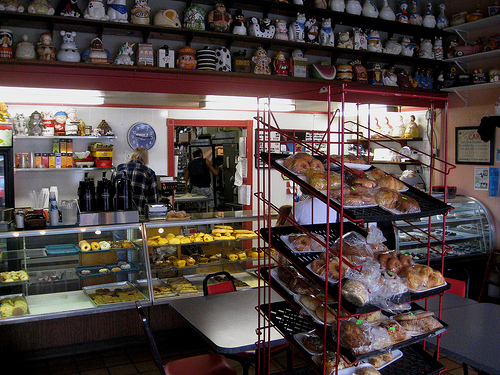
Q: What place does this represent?
A: It represents the bakery.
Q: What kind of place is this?
A: It is a bakery.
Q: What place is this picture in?
A: It is at the bakery.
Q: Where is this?
A: This is at the bakery.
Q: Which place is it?
A: It is a bakery.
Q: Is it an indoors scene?
A: Yes, it is indoors.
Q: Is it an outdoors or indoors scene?
A: It is indoors.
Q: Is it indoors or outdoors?
A: It is indoors.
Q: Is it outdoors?
A: No, it is indoors.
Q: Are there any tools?
A: No, there are no tools.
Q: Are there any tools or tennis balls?
A: No, there are no tools or tennis balls.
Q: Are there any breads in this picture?
A: Yes, there is a bread.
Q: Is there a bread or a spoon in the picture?
A: Yes, there is a bread.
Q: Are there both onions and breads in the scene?
A: No, there is a bread but no onions.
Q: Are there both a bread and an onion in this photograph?
A: No, there is a bread but no onions.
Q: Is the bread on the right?
A: Yes, the bread is on the right of the image.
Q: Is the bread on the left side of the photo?
A: No, the bread is on the right of the image.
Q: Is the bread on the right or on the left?
A: The bread is on the right of the image.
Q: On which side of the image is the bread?
A: The bread is on the right of the image.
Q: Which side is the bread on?
A: The bread is on the right of the image.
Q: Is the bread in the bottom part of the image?
A: Yes, the bread is in the bottom of the image.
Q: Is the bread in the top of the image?
A: No, the bread is in the bottom of the image.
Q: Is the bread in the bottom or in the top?
A: The bread is in the bottom of the image.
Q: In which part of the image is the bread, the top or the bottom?
A: The bread is in the bottom of the image.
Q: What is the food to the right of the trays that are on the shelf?
A: The food is a bread.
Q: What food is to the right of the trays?
A: The food is a bread.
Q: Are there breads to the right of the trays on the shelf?
A: Yes, there is a bread to the right of the trays.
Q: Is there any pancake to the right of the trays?
A: No, there is a bread to the right of the trays.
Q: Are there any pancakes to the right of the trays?
A: No, there is a bread to the right of the trays.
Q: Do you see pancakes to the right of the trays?
A: No, there is a bread to the right of the trays.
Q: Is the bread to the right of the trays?
A: Yes, the bread is to the right of the trays.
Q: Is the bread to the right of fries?
A: No, the bread is to the right of the trays.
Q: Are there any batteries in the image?
A: No, there are no batteries.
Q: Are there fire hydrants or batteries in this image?
A: No, there are no batteries or fire hydrants.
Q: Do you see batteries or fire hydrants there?
A: No, there are no batteries or fire hydrants.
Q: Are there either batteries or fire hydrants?
A: No, there are no batteries or fire hydrants.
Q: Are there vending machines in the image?
A: No, there are no vending machines.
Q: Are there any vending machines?
A: No, there are no vending machines.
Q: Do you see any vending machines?
A: No, there are no vending machines.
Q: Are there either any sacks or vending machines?
A: No, there are no vending machines or sacks.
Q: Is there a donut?
A: Yes, there is a donut.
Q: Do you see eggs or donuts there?
A: Yes, there is a donut.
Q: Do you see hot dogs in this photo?
A: No, there are no hot dogs.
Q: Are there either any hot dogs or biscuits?
A: No, there are no hot dogs or biscuits.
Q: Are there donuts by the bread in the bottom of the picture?
A: Yes, there is a donut by the bread.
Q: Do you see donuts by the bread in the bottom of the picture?
A: Yes, there is a donut by the bread.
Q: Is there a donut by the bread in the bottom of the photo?
A: Yes, there is a donut by the bread.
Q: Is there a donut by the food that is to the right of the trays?
A: Yes, there is a donut by the bread.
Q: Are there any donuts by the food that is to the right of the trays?
A: Yes, there is a donut by the bread.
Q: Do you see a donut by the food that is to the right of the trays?
A: Yes, there is a donut by the bread.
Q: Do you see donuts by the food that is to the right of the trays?
A: Yes, there is a donut by the bread.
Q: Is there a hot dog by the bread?
A: No, there is a donut by the bread.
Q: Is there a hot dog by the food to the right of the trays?
A: No, there is a donut by the bread.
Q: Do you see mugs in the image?
A: No, there are no mugs.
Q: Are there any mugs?
A: No, there are no mugs.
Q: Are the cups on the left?
A: Yes, the cups are on the left of the image.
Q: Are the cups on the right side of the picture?
A: No, the cups are on the left of the image.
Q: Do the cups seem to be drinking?
A: Yes, the cups are drinking.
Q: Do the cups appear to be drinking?
A: Yes, the cups are drinking.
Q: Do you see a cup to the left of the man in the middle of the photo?
A: Yes, there are cups to the left of the man.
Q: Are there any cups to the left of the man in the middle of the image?
A: Yes, there are cups to the left of the man.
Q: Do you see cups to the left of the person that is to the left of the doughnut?
A: Yes, there are cups to the left of the man.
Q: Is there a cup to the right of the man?
A: No, the cups are to the left of the man.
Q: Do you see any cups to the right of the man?
A: No, the cups are to the left of the man.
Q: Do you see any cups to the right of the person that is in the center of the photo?
A: No, the cups are to the left of the man.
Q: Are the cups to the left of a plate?
A: No, the cups are to the left of the man.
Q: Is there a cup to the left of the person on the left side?
A: Yes, there are cups to the left of the person.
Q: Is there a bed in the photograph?
A: No, there are no beds.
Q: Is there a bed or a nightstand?
A: No, there are no beds or nightstands.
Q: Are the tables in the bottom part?
A: Yes, the tables are in the bottom of the image.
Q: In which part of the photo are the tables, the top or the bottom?
A: The tables are in the bottom of the image.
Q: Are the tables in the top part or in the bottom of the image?
A: The tables are in the bottom of the image.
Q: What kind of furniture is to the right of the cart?
A: The pieces of furniture are tables.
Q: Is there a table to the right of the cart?
A: Yes, there are tables to the right of the cart.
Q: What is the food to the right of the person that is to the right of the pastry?
A: The food is bagels.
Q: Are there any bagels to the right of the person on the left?
A: Yes, there are bagels to the right of the person.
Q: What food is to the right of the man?
A: The food is bagels.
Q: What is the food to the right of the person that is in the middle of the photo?
A: The food is bagels.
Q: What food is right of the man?
A: The food is bagels.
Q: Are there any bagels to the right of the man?
A: Yes, there are bagels to the right of the man.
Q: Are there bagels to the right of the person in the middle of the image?
A: Yes, there are bagels to the right of the man.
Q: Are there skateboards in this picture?
A: No, there are no skateboards.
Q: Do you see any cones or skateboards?
A: No, there are no skateboards or cones.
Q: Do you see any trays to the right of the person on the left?
A: Yes, there are trays to the right of the person.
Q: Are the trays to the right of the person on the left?
A: Yes, the trays are to the right of the person.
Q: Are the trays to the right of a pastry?
A: Yes, the trays are to the right of a pastry.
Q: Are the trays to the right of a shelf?
A: Yes, the trays are to the right of a shelf.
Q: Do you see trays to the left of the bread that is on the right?
A: Yes, there are trays to the left of the bread.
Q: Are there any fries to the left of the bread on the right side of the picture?
A: No, there are trays to the left of the bread.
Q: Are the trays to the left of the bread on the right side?
A: Yes, the trays are to the left of the bread.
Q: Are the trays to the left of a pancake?
A: No, the trays are to the left of the bread.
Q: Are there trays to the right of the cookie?
A: Yes, there are trays to the right of the cookie.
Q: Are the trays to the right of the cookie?
A: Yes, the trays are to the right of the cookie.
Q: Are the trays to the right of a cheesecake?
A: No, the trays are to the right of the cookie.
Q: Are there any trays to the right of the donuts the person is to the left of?
A: Yes, there are trays to the right of the donuts.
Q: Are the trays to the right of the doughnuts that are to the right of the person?
A: Yes, the trays are to the right of the doughnuts.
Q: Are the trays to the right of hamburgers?
A: No, the trays are to the right of the doughnuts.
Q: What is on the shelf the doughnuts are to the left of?
A: The trays are on the shelf.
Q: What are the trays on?
A: The trays are on the shelf.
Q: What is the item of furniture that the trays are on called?
A: The piece of furniture is a shelf.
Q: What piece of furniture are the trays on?
A: The trays are on the shelf.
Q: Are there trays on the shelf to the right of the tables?
A: Yes, there are trays on the shelf.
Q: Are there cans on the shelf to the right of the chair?
A: No, there are trays on the shelf.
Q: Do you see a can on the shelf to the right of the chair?
A: No, there are trays on the shelf.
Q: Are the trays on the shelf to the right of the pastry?
A: Yes, the trays are on the shelf.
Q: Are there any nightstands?
A: No, there are no nightstands.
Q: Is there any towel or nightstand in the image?
A: No, there are no nightstands or towels.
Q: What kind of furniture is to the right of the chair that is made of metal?
A: The piece of furniture is a shelf.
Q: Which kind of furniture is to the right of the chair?
A: The piece of furniture is a shelf.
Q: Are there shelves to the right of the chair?
A: Yes, there is a shelf to the right of the chair.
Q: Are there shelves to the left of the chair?
A: No, the shelf is to the right of the chair.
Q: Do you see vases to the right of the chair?
A: No, there is a shelf to the right of the chair.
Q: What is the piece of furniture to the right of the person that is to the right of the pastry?
A: The piece of furniture is a shelf.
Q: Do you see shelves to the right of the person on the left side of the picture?
A: Yes, there is a shelf to the right of the person.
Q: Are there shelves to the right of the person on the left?
A: Yes, there is a shelf to the right of the person.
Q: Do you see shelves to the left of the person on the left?
A: No, the shelf is to the right of the person.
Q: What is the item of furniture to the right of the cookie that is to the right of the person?
A: The piece of furniture is a shelf.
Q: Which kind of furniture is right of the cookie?
A: The piece of furniture is a shelf.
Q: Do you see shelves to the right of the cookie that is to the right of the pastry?
A: Yes, there is a shelf to the right of the cookie.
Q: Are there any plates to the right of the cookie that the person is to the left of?
A: No, there is a shelf to the right of the cookie.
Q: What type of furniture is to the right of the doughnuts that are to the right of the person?
A: The piece of furniture is a shelf.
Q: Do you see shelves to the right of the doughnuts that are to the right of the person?
A: Yes, there is a shelf to the right of the doughnuts.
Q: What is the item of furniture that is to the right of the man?
A: The piece of furniture is a shelf.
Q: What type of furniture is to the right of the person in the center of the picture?
A: The piece of furniture is a shelf.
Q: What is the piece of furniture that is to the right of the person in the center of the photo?
A: The piece of furniture is a shelf.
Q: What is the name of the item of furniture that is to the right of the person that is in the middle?
A: The piece of furniture is a shelf.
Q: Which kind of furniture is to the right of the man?
A: The piece of furniture is a shelf.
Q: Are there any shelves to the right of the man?
A: Yes, there is a shelf to the right of the man.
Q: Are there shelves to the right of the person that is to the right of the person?
A: Yes, there is a shelf to the right of the man.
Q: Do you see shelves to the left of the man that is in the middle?
A: No, the shelf is to the right of the man.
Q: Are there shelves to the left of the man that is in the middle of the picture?
A: No, the shelf is to the right of the man.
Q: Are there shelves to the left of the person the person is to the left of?
A: No, the shelf is to the right of the man.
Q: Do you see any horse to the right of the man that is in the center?
A: No, there is a shelf to the right of the man.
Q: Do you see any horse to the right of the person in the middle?
A: No, there is a shelf to the right of the man.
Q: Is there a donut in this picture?
A: Yes, there are donuts.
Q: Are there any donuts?
A: Yes, there are donuts.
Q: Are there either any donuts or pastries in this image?
A: Yes, there are donuts.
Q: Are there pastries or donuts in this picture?
A: Yes, there are donuts.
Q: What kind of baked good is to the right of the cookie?
A: The food is donuts.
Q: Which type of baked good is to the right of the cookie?
A: The food is donuts.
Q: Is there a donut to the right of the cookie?
A: Yes, there are donuts to the right of the cookie.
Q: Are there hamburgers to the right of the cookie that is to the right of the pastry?
A: No, there are donuts to the right of the cookie.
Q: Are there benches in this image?
A: No, there are no benches.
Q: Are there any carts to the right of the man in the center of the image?
A: Yes, there is a cart to the right of the man.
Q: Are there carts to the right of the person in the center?
A: Yes, there is a cart to the right of the man.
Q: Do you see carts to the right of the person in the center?
A: Yes, there is a cart to the right of the man.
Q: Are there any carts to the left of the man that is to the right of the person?
A: No, the cart is to the right of the man.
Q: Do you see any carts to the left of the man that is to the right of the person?
A: No, the cart is to the right of the man.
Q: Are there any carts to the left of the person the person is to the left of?
A: No, the cart is to the right of the man.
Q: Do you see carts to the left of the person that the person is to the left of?
A: No, the cart is to the right of the man.